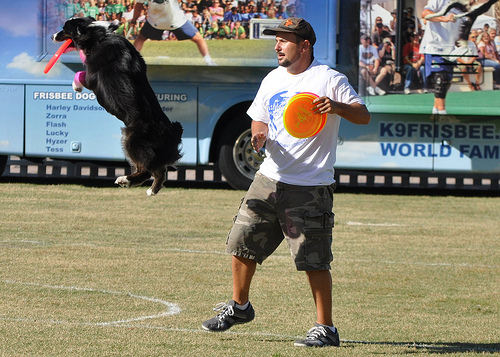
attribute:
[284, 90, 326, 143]
frisbee — orange, red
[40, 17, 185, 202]
dog — jumping, black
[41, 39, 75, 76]
frisbee — red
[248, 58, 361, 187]
shirt — white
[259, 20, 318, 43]
cap — grey, brown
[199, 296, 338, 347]
shoes — grey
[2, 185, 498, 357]
playground — green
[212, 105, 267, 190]
wheel — black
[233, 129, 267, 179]
hub cap — metallic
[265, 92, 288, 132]
lettering — blue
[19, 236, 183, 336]
lines — white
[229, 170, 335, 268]
shorts — camouflage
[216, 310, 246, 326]
stripes — white